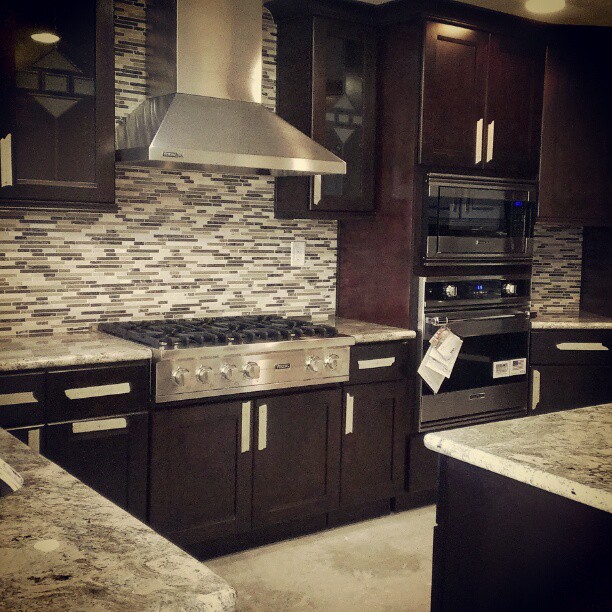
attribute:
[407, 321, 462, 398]
discloths — white